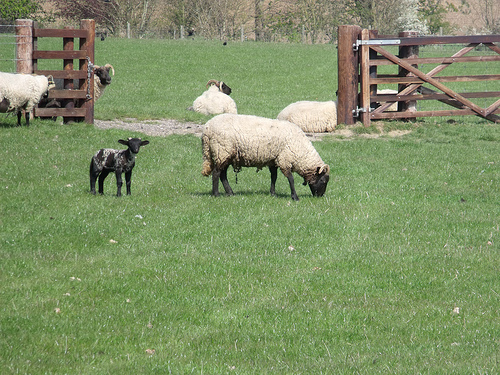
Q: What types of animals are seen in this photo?
A: Sheep.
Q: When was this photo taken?
A: Daytime.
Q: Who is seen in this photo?
A: No One.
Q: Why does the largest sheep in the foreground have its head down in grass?
A: Grazing.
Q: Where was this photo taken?
A: Pasture.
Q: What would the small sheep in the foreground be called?
A: Lamb.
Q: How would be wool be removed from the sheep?
A: Be shearing.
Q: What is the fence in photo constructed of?
A: Wood.